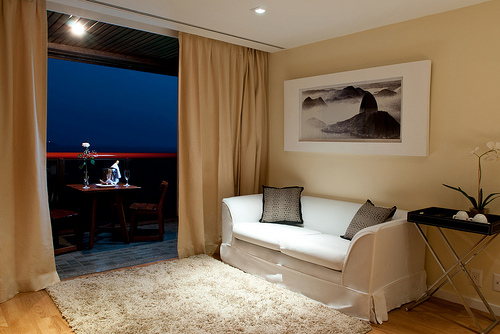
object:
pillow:
[340, 199, 397, 241]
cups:
[468, 214, 489, 224]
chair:
[129, 181, 169, 242]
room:
[0, 0, 500, 334]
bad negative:
[352, 158, 373, 179]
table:
[67, 183, 142, 248]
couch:
[219, 193, 427, 325]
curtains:
[176, 31, 270, 258]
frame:
[283, 59, 431, 157]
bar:
[45, 152, 177, 160]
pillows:
[259, 185, 304, 224]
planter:
[469, 208, 489, 219]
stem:
[474, 152, 484, 207]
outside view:
[39, 60, 176, 215]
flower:
[463, 140, 500, 160]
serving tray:
[407, 207, 500, 236]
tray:
[408, 200, 493, 241]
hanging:
[272, 55, 457, 160]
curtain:
[1, 0, 60, 305]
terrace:
[45, 34, 180, 281]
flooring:
[383, 302, 496, 332]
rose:
[82, 142, 91, 147]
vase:
[83, 171, 90, 189]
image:
[300, 80, 401, 142]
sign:
[89, 153, 115, 158]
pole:
[45, 152, 180, 159]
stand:
[403, 206, 499, 333]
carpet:
[45, 254, 374, 334]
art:
[300, 79, 402, 142]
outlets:
[469, 268, 483, 288]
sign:
[300, 80, 403, 144]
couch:
[222, 187, 426, 317]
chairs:
[50, 209, 84, 256]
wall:
[265, 2, 496, 316]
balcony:
[47, 150, 182, 279]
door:
[44, 10, 179, 271]